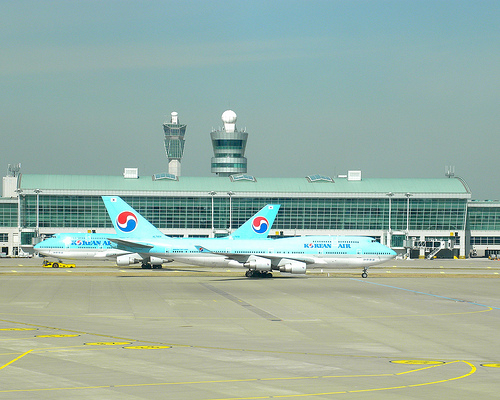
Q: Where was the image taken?
A: It was taken at the airport.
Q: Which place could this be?
A: It is an airport.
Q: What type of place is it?
A: It is an airport.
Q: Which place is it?
A: It is an airport.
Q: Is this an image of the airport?
A: Yes, it is showing the airport.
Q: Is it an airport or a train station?
A: It is an airport.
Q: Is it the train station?
A: No, it is the airport.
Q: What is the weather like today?
A: It is clear.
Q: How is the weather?
A: It is clear.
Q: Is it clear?
A: Yes, it is clear.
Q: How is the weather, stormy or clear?
A: It is clear.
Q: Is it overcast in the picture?
A: No, it is clear.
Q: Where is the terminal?
A: The terminal is at the airport.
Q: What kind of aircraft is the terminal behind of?
A: The terminal is behind the airplane.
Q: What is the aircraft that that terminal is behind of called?
A: The aircraft is an airplane.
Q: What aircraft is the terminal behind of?
A: The terminal is behind the airplane.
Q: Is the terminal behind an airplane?
A: Yes, the terminal is behind an airplane.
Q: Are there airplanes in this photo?
A: Yes, there is an airplane.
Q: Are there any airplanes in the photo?
A: Yes, there is an airplane.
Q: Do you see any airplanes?
A: Yes, there is an airplane.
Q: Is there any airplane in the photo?
A: Yes, there is an airplane.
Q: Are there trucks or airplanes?
A: Yes, there is an airplane.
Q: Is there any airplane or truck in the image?
A: Yes, there is an airplane.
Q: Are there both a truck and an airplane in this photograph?
A: No, there is an airplane but no trucks.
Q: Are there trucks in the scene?
A: No, there are no trucks.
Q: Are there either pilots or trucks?
A: No, there are no trucks or pilots.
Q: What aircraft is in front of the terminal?
A: The aircraft is an airplane.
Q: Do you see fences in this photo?
A: No, there are no fences.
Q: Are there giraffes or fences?
A: No, there are no fences or giraffes.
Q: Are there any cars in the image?
A: No, there are no cars.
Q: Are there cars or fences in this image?
A: No, there are no cars or fences.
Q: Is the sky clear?
A: Yes, the sky is clear.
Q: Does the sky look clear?
A: Yes, the sky is clear.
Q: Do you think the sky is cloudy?
A: No, the sky is clear.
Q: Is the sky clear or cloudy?
A: The sky is clear.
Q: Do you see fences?
A: No, there are no fences.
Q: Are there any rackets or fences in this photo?
A: No, there are no fences or rackets.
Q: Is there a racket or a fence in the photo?
A: No, there are no fences or rackets.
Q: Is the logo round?
A: Yes, the logo is round.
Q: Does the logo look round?
A: Yes, the logo is round.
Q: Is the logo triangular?
A: No, the logo is round.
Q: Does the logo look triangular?
A: No, the logo is round.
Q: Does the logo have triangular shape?
A: No, the logo is round.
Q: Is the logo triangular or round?
A: The logo is round.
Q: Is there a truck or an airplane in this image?
A: Yes, there is an airplane.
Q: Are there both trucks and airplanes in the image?
A: No, there is an airplane but no trucks.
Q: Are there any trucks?
A: No, there are no trucks.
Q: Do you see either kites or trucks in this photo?
A: No, there are no trucks or kites.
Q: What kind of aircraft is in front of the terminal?
A: The aircraft is an airplane.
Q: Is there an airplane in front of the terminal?
A: Yes, there is an airplane in front of the terminal.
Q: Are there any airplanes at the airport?
A: Yes, there is an airplane at the airport.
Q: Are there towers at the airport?
A: No, there is an airplane at the airport.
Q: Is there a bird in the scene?
A: No, there are no birds.